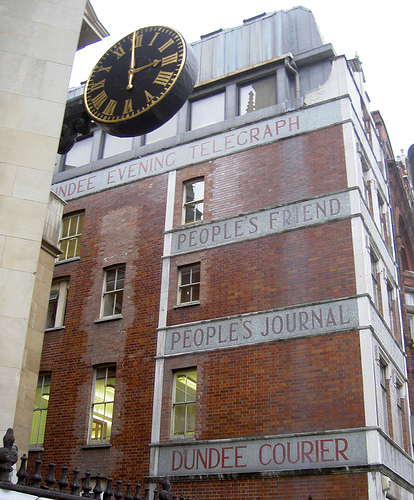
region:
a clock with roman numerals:
[78, 15, 203, 153]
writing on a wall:
[153, 433, 380, 477]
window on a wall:
[159, 358, 214, 442]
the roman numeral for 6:
[118, 96, 137, 119]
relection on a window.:
[151, 160, 226, 239]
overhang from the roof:
[53, 2, 121, 51]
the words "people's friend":
[154, 179, 360, 263]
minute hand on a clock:
[124, 30, 139, 98]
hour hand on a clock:
[121, 52, 174, 80]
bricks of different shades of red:
[247, 348, 355, 411]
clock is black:
[84, 22, 197, 136]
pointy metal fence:
[0, 426, 218, 496]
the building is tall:
[47, 11, 411, 497]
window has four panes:
[165, 364, 205, 445]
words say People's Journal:
[159, 298, 373, 350]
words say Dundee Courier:
[157, 431, 378, 473]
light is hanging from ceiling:
[39, 389, 118, 431]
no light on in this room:
[37, 254, 213, 327]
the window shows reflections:
[177, 173, 217, 227]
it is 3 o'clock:
[80, 18, 199, 141]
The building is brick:
[21, 96, 411, 494]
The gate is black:
[0, 425, 177, 496]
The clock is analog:
[80, 22, 197, 140]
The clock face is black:
[80, 23, 199, 136]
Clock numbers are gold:
[80, 24, 183, 124]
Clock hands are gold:
[118, 26, 162, 91]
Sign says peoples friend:
[169, 195, 344, 250]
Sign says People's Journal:
[166, 301, 347, 354]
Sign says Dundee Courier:
[165, 432, 352, 472]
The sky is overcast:
[68, 0, 412, 154]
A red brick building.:
[44, 153, 389, 438]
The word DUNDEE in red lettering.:
[167, 441, 254, 477]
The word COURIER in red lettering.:
[251, 431, 363, 470]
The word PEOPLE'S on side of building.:
[166, 317, 265, 353]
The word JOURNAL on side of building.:
[256, 301, 358, 343]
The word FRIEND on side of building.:
[264, 197, 356, 230]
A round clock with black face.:
[76, 17, 197, 142]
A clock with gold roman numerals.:
[84, 11, 196, 131]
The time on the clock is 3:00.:
[81, 7, 205, 137]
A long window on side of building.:
[72, 344, 129, 461]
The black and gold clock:
[83, 24, 198, 132]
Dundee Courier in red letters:
[150, 431, 374, 468]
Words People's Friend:
[162, 194, 359, 257]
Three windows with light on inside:
[35, 365, 195, 440]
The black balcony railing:
[1, 427, 172, 499]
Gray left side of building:
[0, 1, 108, 229]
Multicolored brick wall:
[199, 350, 356, 432]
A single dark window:
[174, 260, 209, 312]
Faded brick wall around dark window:
[82, 210, 144, 359]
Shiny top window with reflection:
[239, 69, 285, 113]